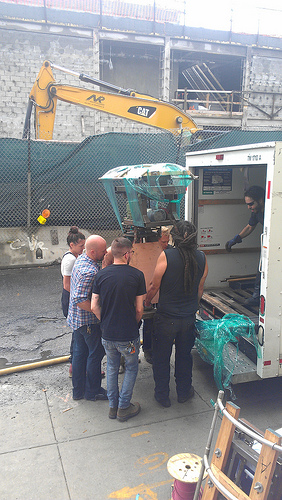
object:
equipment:
[98, 161, 197, 318]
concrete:
[108, 396, 184, 475]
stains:
[81, 420, 187, 499]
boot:
[108, 403, 117, 420]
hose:
[0, 353, 71, 377]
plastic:
[193, 312, 261, 412]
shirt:
[66, 252, 100, 330]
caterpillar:
[36, 204, 52, 224]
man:
[225, 184, 264, 251]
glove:
[223, 233, 242, 253]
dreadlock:
[170, 218, 199, 294]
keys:
[125, 338, 135, 351]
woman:
[60, 226, 86, 377]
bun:
[66, 224, 86, 248]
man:
[67, 234, 107, 399]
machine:
[23, 59, 199, 139]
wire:
[170, 479, 196, 498]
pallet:
[202, 401, 282, 499]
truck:
[184, 141, 281, 383]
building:
[0, 0, 280, 140]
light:
[213, 152, 224, 160]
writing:
[132, 448, 173, 495]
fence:
[0, 124, 282, 242]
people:
[144, 220, 209, 407]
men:
[91, 237, 147, 421]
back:
[165, 251, 204, 317]